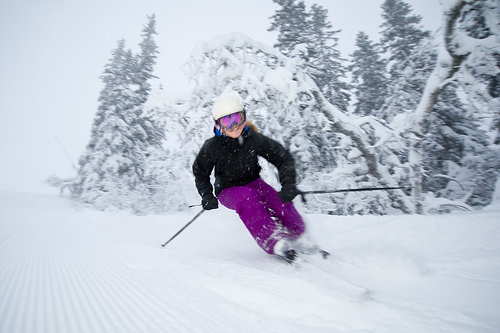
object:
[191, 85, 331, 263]
skier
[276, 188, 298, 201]
hand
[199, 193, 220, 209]
glove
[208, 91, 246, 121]
white helmet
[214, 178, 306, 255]
purple pants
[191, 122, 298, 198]
black coat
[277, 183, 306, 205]
glove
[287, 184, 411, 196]
ski pole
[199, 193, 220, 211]
skier's right hand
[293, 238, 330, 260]
skier's left boot.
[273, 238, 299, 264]
e skier's right boot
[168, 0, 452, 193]
white clouds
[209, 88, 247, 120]
wearing white helmet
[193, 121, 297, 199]
wearing black jacket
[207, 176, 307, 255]
wearing purple pants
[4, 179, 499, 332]
snow on mountain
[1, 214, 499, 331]
"white snow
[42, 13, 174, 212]
green trees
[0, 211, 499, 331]
ground covered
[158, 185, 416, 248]
pair of skis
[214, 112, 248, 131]
purple goggles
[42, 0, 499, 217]
covered in snow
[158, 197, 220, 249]
holding ski stick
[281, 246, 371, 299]
under skiers feet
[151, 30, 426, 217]
tree with no leaves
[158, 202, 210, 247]
skiing pole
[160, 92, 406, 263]
young girl is skiing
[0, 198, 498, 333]
snowy slopes